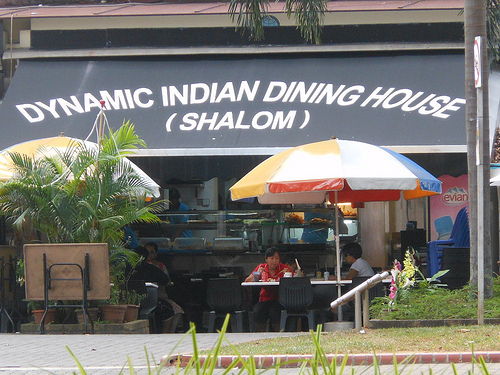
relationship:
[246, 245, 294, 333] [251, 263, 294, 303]
woman with shirt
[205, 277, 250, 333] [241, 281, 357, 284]
chair at counter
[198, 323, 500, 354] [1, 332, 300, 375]
grass beside sidewalk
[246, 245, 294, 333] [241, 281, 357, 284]
woman at counter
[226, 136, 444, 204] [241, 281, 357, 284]
umbrella over counter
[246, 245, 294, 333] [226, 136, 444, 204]
woman under umbrella